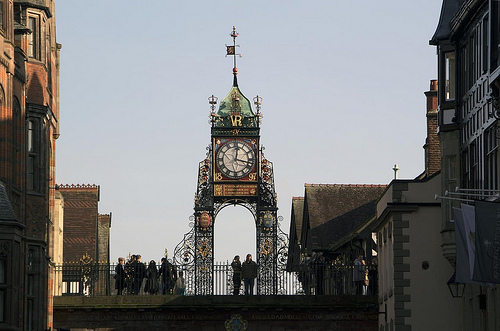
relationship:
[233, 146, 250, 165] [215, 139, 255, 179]
black hands on clock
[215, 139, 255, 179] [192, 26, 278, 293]
clock on tower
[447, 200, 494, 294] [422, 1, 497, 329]
flag hanging from building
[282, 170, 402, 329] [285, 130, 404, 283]
building has roof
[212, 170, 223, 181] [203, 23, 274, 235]
number 18 on tower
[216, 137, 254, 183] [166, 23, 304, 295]
clock in tower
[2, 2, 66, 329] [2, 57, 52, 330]
building has shadow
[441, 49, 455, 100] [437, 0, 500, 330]
window on building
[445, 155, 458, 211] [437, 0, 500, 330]
window on building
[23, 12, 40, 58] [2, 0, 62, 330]
window on building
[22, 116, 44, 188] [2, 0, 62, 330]
window on building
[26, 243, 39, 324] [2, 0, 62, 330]
window on building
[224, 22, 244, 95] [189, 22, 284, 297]
weather vane on top of tower